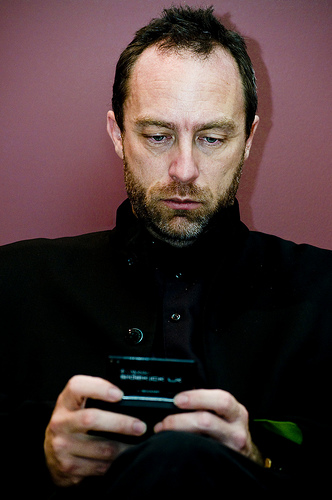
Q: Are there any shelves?
A: No, there are no shelves.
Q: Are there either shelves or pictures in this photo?
A: No, there are no shelves or pictures.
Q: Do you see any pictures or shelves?
A: No, there are no shelves or pictures.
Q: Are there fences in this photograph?
A: No, there are no fences.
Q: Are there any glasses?
A: No, there are no glasses.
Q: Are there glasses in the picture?
A: No, there are no glasses.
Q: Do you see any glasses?
A: No, there are no glasses.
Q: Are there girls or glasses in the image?
A: No, there are no glasses or girls.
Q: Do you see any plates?
A: No, there are no plates.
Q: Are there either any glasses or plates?
A: No, there are no plates or glasses.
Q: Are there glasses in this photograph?
A: No, there are no glasses.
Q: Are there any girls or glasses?
A: No, there are no glasses or girls.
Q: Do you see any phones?
A: Yes, there is a phone.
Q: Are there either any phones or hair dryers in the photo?
A: Yes, there is a phone.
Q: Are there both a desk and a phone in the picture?
A: No, there is a phone but no desks.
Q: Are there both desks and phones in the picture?
A: No, there is a phone but no desks.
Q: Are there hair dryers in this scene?
A: No, there are no hair dryers.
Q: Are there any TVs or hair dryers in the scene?
A: No, there are no hair dryers or tvs.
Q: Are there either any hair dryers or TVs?
A: No, there are no hair dryers or tvs.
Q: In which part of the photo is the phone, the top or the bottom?
A: The phone is in the bottom of the image.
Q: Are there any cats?
A: No, there are no cats.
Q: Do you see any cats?
A: No, there are no cats.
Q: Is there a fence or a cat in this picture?
A: No, there are no cats or fences.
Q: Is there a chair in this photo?
A: No, there are no chairs.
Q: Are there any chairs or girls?
A: No, there are no chairs or girls.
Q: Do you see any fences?
A: No, there are no fences.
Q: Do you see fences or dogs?
A: No, there are no fences or dogs.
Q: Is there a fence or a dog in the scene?
A: No, there are no fences or dogs.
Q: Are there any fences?
A: No, there are no fences.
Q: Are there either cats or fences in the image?
A: No, there are no fences or cats.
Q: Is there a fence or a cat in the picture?
A: No, there are no fences or cats.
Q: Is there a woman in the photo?
A: No, there are no women.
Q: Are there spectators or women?
A: No, there are no women or spectators.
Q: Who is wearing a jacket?
A: The man is wearing a jacket.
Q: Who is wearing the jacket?
A: The man is wearing a jacket.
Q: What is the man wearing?
A: The man is wearing a jacket.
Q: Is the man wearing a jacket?
A: Yes, the man is wearing a jacket.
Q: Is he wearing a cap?
A: No, the man is wearing a jacket.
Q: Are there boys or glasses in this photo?
A: No, there are no glasses or boys.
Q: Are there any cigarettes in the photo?
A: No, there are no cigarettes.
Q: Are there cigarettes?
A: No, there are no cigarettes.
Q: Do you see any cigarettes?
A: No, there are no cigarettes.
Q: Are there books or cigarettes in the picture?
A: No, there are no cigarettes or books.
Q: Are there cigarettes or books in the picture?
A: No, there are no cigarettes or books.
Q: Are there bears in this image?
A: No, there are no bears.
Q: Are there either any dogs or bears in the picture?
A: No, there are no bears or dogs.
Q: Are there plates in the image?
A: No, there are no plates.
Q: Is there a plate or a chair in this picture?
A: No, there are no plates or chairs.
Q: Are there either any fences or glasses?
A: No, there are no fences or glasses.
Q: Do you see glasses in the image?
A: No, there are no glasses.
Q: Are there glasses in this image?
A: No, there are no glasses.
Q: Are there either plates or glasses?
A: No, there are no glasses or plates.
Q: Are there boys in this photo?
A: No, there are no boys.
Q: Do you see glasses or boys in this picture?
A: No, there are no boys or glasses.